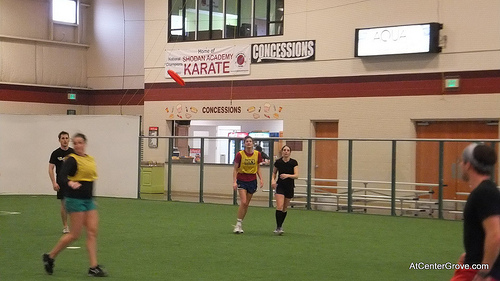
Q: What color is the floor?
A: Green.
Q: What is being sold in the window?
A: Concessions.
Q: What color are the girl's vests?
A: Yellow.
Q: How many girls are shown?
A: Three.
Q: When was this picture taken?
A: Daytime.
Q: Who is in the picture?
A: Boys and girls.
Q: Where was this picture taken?
A: A gym.